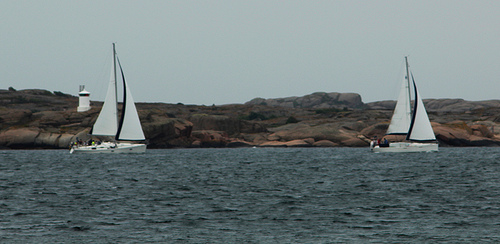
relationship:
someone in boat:
[379, 134, 388, 146] [368, 56, 438, 152]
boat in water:
[368, 55, 440, 154] [1, 146, 499, 242]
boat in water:
[66, 42, 146, 155] [1, 146, 499, 242]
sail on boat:
[407, 71, 442, 142] [368, 55, 440, 154]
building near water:
[76, 84, 92, 112] [1, 146, 499, 242]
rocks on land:
[281, 75, 371, 130] [1, 84, 499, 150]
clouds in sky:
[0, 0, 500, 106] [3, 3, 493, 95]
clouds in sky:
[3, 10, 494, 87] [3, 3, 493, 95]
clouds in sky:
[0, 0, 500, 106] [2, 0, 499, 105]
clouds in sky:
[0, 0, 500, 106] [153, 3, 326, 105]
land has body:
[5, 78, 485, 153] [17, 90, 482, 140]